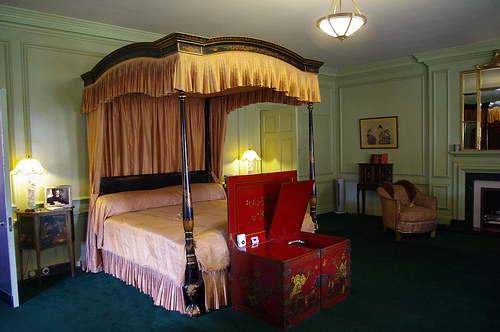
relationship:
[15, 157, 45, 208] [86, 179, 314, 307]
lamp beside bed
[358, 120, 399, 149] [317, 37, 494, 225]
painting on wall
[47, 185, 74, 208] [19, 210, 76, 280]
frame on table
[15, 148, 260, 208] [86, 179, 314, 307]
lamps near bed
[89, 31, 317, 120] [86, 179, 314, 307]
canopy over bed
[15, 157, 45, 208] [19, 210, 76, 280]
lamp on table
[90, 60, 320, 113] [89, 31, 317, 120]
ruffle on canopy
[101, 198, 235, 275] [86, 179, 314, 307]
bedspread on bed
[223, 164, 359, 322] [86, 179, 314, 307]
chest near bed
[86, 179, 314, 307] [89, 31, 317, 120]
bed has canopy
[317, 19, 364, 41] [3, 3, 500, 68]
light on ceiling